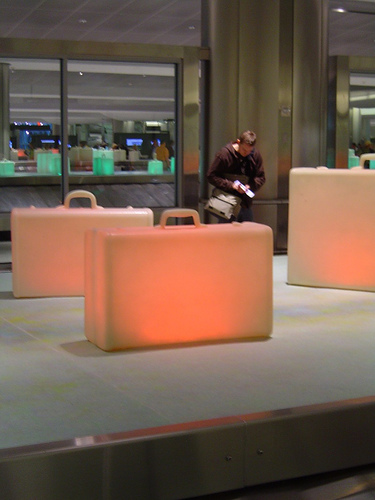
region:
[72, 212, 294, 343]
suitcase statue on ground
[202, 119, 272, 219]
man near suitcase statues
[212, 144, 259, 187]
jacket on the man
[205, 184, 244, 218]
bag on the man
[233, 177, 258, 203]
item in man's hand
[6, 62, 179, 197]
window to a building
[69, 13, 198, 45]
lights on the ceiling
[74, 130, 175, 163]
people inside a building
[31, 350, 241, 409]
sidewalk in front of building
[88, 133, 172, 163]
people inside the building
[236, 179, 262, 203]
Paper in the mans hand.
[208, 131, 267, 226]
A man standing up.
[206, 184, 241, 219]
The tan messenger bag.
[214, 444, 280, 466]
The two bolts.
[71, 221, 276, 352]
The large luminated suitcase.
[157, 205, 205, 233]
A luminated suitcase handle.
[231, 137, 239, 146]
The mans right ear.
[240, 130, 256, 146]
The mans brown hair.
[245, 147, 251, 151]
The mans left eye.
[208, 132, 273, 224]
man standing on sidewalk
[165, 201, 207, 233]
white handle on suitcase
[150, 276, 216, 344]
orange glow on suitcase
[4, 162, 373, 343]
three whtie suitcases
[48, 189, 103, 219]
handle to white suitcase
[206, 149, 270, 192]
brown jacket on man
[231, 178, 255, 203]
paper in hand of man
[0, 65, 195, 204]
large window on side of building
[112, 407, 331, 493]
silver beam on end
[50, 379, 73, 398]
yellow paint on platform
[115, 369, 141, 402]
yellow paint on platform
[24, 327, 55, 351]
yellow paint on platform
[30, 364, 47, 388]
yellow paint on platform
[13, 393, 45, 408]
yellow paint on platform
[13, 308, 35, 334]
yellow paint on platform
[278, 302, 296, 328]
yellow paint on platform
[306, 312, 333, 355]
yellow paint on platform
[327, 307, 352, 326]
yellow paint on platform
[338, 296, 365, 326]
yellow paint on platform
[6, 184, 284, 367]
briedcases on platform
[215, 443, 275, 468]
nails in platform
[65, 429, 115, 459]
light reflected on metal platform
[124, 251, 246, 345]
orange light glowing through briefcase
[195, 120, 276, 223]
person standing on sidewalk looking down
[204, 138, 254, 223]
tan and black messenger bag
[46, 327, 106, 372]
back shadow of briedcase on platform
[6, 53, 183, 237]
double pane window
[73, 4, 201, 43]
recessed lighting on ceiling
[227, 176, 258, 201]
white object in person's hand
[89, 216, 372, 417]
a suitcase is lit up